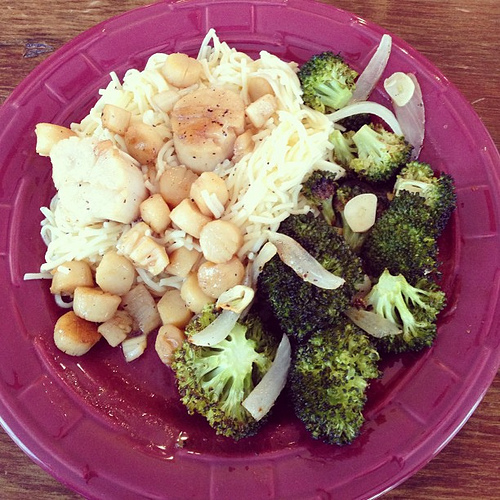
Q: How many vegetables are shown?
A: One.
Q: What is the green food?
A: Broccoli.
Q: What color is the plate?
A: Purple.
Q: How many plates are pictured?
A: One.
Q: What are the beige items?
A: Scallops.